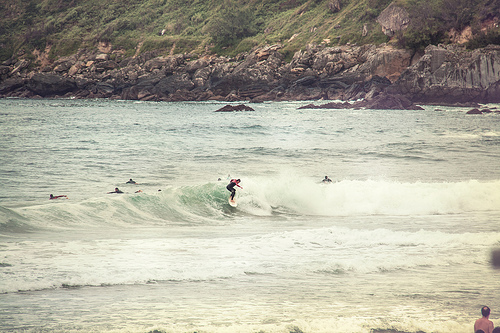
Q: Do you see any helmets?
A: No, there are no helmets.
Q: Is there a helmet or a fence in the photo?
A: No, there are no helmets or fences.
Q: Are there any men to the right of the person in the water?
A: Yes, there is a man to the right of the person.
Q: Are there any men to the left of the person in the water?
A: No, the man is to the right of the person.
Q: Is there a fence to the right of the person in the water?
A: No, there is a man to the right of the person.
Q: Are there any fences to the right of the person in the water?
A: No, there is a man to the right of the person.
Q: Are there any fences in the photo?
A: No, there are no fences.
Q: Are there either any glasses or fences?
A: No, there are no fences or glasses.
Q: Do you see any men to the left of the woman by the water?
A: Yes, there is a man to the left of the woman.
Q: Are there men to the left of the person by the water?
A: Yes, there is a man to the left of the woman.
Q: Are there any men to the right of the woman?
A: No, the man is to the left of the woman.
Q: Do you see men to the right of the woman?
A: No, the man is to the left of the woman.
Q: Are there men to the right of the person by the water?
A: No, the man is to the left of the woman.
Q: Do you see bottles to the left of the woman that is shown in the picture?
A: No, there is a man to the left of the woman.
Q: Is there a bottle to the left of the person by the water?
A: No, there is a man to the left of the woman.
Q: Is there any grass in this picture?
A: Yes, there is grass.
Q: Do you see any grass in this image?
A: Yes, there is grass.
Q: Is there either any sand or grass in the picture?
A: Yes, there is grass.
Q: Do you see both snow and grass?
A: No, there is grass but no snow.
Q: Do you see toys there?
A: No, there are no toys.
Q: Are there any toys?
A: No, there are no toys.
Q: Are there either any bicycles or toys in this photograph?
A: No, there are no toys or bicycles.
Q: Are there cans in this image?
A: No, there are no cans.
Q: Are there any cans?
A: No, there are no cans.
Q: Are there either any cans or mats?
A: No, there are no cans or mats.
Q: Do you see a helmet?
A: No, there are no helmets.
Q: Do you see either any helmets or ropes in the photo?
A: No, there are no helmets or ropes.